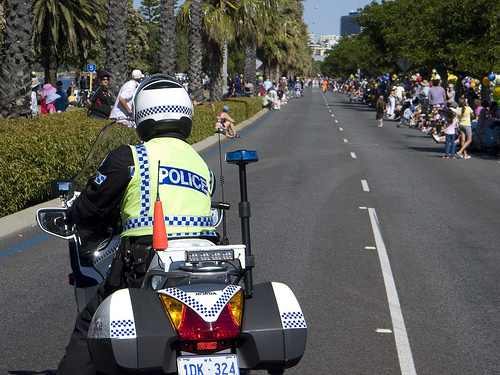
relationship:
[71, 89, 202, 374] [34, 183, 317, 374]
policeman riding bike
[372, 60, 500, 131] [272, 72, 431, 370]
spectators near street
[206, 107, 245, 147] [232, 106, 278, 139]
people sitting on curb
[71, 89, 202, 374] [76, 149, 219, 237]
policeman has jacket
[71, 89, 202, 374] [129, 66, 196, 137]
policeman wears helmet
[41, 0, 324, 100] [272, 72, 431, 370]
palms near street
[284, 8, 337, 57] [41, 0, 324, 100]
buildings near palms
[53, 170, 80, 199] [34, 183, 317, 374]
camera on bike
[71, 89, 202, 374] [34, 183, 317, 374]
policeman sits on bike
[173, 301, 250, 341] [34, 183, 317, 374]
lights on rear of bike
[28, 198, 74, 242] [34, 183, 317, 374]
rearview mirror on side of bike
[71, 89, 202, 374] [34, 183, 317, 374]
policeman sitting on bike